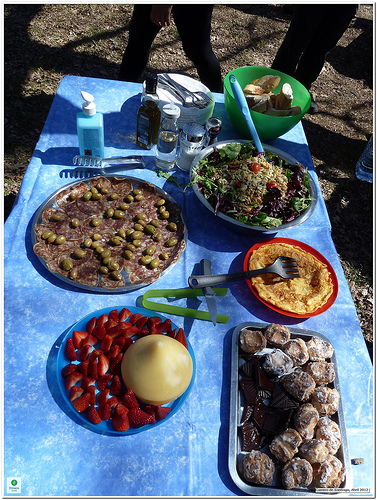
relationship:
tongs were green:
[137, 267, 238, 330] [145, 280, 228, 321]